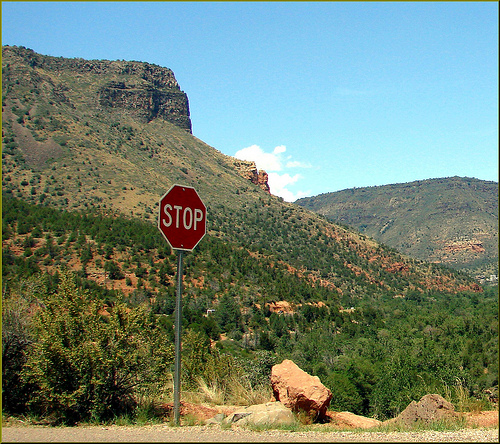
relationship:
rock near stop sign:
[265, 356, 333, 422] [155, 180, 209, 425]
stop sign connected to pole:
[155, 180, 209, 425] [173, 245, 184, 427]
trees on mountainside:
[1, 123, 499, 415] [6, 43, 492, 440]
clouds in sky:
[231, 135, 319, 207] [5, 5, 493, 196]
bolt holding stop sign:
[179, 184, 191, 195] [155, 180, 209, 425]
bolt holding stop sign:
[173, 241, 190, 252] [155, 180, 209, 425]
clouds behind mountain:
[231, 135, 319, 207] [140, 118, 270, 433]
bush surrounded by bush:
[0, 279, 35, 383] [1, 263, 175, 428]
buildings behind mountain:
[474, 269, 498, 290] [0, 37, 291, 399]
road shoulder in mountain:
[3, 397, 499, 442] [140, 118, 270, 433]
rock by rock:
[265, 356, 333, 422] [390, 389, 452, 430]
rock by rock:
[265, 356, 333, 422] [219, 403, 294, 430]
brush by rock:
[172, 362, 272, 415] [265, 356, 333, 422]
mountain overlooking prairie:
[0, 37, 291, 399] [241, 257, 499, 420]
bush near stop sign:
[1, 263, 175, 428] [155, 180, 209, 425]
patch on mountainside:
[263, 291, 307, 318] [6, 43, 492, 440]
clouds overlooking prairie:
[231, 135, 319, 207] [241, 257, 499, 420]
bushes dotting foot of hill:
[3, 203, 472, 340] [5, 169, 483, 360]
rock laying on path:
[265, 356, 333, 422] [5, 416, 488, 442]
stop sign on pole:
[155, 180, 209, 425] [173, 245, 184, 427]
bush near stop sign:
[0, 279, 35, 383] [155, 180, 209, 425]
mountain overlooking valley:
[0, 37, 291, 399] [415, 243, 497, 301]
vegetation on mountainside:
[7, 49, 416, 303] [6, 43, 492, 440]